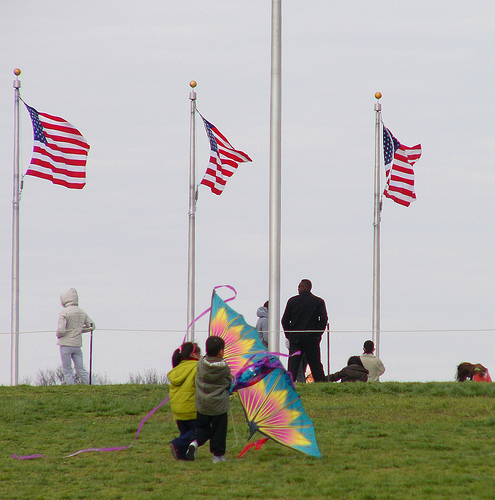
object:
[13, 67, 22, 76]
ball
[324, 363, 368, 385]
jacket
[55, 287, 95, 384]
person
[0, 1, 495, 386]
sky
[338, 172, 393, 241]
ground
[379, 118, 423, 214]
american flag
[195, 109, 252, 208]
american flag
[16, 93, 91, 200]
american flag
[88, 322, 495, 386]
fence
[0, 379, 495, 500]
hill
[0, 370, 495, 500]
grass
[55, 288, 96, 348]
jacket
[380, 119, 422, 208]
flag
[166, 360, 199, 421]
jacket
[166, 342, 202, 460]
child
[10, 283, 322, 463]
kite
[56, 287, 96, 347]
coat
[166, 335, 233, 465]
children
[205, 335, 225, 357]
hair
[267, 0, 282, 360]
flagpole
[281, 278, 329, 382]
person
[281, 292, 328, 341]
jacket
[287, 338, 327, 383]
pants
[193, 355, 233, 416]
jacket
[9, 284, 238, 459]
tail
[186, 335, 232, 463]
boy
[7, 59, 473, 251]
wind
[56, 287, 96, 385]
outfit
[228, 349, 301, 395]
ribbons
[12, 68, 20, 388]
pole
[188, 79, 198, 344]
pole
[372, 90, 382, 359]
pole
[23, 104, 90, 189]
flag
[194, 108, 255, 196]
flag